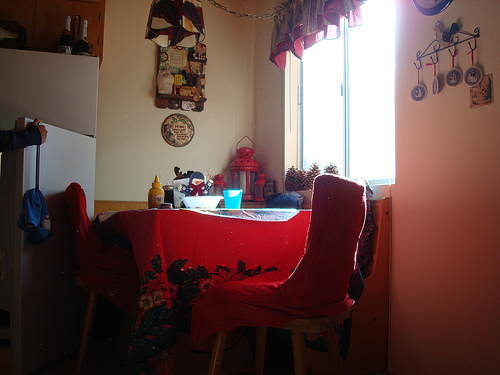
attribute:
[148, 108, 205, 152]
decoration — round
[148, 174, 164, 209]
bottle — yellow, plastic, short, round, squeeze bottle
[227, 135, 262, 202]
lantern — red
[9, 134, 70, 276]
towel — blue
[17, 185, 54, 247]
towel — blue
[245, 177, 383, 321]
cover — red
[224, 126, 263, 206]
lantern — large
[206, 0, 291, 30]
chain — suspended 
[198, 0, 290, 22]
chain — suspended 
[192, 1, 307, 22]
chain — suspended 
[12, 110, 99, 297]
door — open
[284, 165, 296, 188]
cone — brown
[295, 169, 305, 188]
cone — brown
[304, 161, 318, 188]
cone — brown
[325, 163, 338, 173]
cone — brown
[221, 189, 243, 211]
cup — blue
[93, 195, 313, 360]
table cloth — red, floral printed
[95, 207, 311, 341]
tablecloth — red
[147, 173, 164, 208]
bottle — yellow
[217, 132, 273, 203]
lattern — red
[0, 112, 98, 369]
door — open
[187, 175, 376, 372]
chair — wood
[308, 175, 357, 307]
cover —  red 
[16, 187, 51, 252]
towel — blue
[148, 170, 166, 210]
container — yellow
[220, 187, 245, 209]
cup — blue, plastic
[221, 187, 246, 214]
cup — light blue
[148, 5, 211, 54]
lampshade — stained glass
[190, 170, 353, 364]
chair — wooden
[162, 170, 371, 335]
slip — red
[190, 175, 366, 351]
slipcover — red